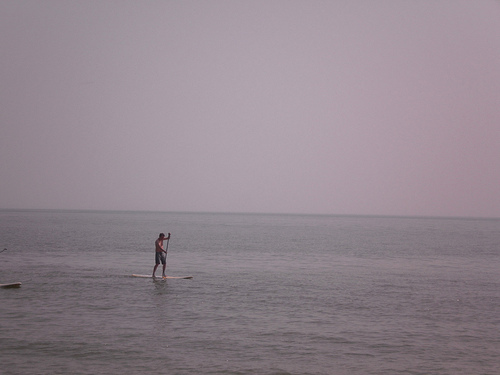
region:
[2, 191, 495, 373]
ocean has waves in it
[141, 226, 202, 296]
the man is paddle boarding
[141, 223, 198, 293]
man not wearing a shirt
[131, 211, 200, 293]
man holding a paddle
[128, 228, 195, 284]
man standing on a board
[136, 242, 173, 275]
man is wearing shorts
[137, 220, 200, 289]
man is by himself in ocean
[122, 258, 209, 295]
the board is white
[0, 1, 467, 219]
the sky is clear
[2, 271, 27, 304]
object in the water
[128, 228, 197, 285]
The man is on a paddle board.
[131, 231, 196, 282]
The man is not wearing a shirt.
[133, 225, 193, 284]
The man is holding a paddle board pole.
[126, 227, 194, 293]
The man is wearing shorts.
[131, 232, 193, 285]
The man's shorts are gray.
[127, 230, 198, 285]
The man's hair is short.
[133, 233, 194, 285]
The man's hair is brown.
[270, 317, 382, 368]
The water is very murky.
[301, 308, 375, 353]
The water is dark in color.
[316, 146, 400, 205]
The sky is gray.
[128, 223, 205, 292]
A man paddleboarding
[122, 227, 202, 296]
A man on a paddle board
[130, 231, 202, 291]
A person on a paddle board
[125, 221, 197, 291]
The male paddling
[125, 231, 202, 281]
The male paddle boarding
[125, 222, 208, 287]
A man standing on a board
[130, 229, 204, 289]
A person standing on a board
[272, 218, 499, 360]
The vast ocean water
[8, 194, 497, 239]
The vast horizon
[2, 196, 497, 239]
The horizon in the distance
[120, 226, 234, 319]
a man on the water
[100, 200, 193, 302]
a man on the water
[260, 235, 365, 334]
the water is calm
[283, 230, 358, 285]
the water is calm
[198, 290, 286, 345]
the water is calm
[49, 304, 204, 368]
the water is calm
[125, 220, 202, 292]
man standing on a surfboard in the ocean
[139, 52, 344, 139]
dark grey sky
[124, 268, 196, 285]
surfboard in the ocean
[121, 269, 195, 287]
surfboard in the water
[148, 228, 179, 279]
man holding onto a pole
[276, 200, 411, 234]
horizon line in the distance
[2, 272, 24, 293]
front part of a surfboard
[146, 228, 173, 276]
man wearing shorts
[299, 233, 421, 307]
calm grey water in the ocean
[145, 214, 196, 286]
man balancing with a pole on a surfboard